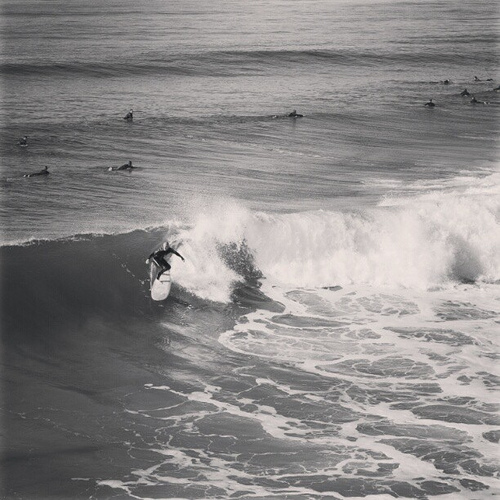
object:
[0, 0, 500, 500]
ocean waters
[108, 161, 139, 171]
person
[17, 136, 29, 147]
person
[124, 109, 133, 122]
person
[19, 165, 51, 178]
person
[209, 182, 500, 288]
sea foam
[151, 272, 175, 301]
surfboard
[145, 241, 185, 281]
man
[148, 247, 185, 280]
wetsuit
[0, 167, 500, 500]
waves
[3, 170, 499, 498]
spray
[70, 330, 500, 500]
ripples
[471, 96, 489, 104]
person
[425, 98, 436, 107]
people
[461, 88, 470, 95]
person swimming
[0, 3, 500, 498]
water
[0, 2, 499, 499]
sea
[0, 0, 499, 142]
floor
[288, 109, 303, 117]
person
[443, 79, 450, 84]
person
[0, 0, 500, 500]
photo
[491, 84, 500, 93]
person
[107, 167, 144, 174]
surfboard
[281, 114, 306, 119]
surfboard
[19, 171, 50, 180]
surfboard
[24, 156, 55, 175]
person